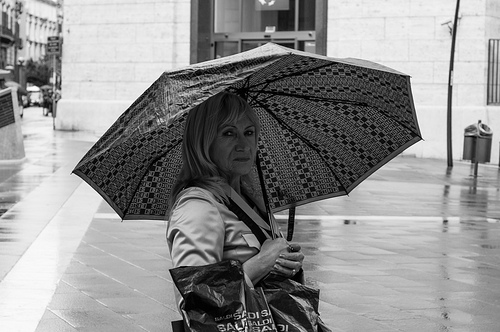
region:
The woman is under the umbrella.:
[128, 74, 325, 209]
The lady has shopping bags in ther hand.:
[148, 219, 338, 325]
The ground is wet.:
[12, 166, 87, 293]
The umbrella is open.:
[130, 55, 402, 187]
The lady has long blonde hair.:
[178, 109, 223, 204]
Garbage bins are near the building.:
[455, 107, 490, 184]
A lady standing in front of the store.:
[105, 65, 420, 320]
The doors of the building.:
[191, 3, 327, 68]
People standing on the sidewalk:
[26, 74, 66, 116]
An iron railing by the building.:
[484, 29, 499, 93]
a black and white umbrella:
[85, 33, 427, 220]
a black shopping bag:
[145, 243, 307, 330]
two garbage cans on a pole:
[453, 111, 497, 181]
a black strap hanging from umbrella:
[280, 194, 312, 257]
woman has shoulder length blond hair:
[170, 95, 275, 216]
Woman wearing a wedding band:
[286, 265, 306, 279]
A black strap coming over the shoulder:
[203, 181, 283, 263]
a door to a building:
[191, 18, 333, 182]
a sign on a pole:
[39, 35, 68, 133]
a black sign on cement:
[2, 87, 18, 139]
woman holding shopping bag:
[183, 111, 318, 329]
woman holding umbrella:
[75, 40, 428, 324]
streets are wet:
[36, 138, 498, 327]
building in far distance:
[0, 4, 62, 119]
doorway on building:
[190, 4, 326, 79]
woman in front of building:
[167, 103, 323, 330]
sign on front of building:
[262, 23, 281, 33]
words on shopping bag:
[194, 300, 311, 330]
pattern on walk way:
[34, 213, 193, 325]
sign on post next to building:
[45, 38, 58, 113]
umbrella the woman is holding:
[68, 51, 451, 223]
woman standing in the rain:
[162, 91, 343, 328]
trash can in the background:
[455, 112, 498, 178]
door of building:
[199, 3, 318, 51]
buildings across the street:
[1, 2, 65, 83]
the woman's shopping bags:
[165, 263, 322, 330]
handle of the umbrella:
[235, 86, 295, 248]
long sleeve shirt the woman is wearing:
[165, 188, 315, 295]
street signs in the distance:
[42, 32, 68, 119]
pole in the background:
[440, 2, 469, 172]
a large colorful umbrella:
[70, 40, 430, 223]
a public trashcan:
[463, 116, 493, 165]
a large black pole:
[439, 0, 462, 165]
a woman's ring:
[289, 267, 298, 274]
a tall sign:
[42, 34, 62, 116]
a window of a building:
[216, 0, 316, 33]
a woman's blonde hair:
[167, 89, 259, 202]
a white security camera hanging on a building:
[437, 15, 448, 32]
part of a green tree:
[9, 57, 54, 84]